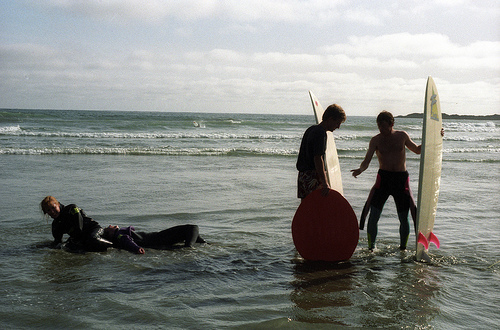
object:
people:
[40, 195, 210, 255]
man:
[295, 104, 347, 204]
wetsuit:
[49, 203, 109, 272]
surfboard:
[413, 77, 447, 254]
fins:
[413, 228, 439, 250]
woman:
[99, 224, 210, 256]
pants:
[366, 171, 413, 249]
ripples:
[93, 263, 258, 308]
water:
[0, 155, 500, 213]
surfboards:
[305, 76, 444, 261]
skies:
[0, 1, 500, 116]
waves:
[86, 115, 174, 147]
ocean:
[0, 103, 500, 152]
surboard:
[306, 88, 345, 204]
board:
[291, 186, 361, 266]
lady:
[39, 194, 114, 253]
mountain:
[395, 105, 500, 118]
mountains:
[397, 105, 497, 138]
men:
[295, 102, 446, 250]